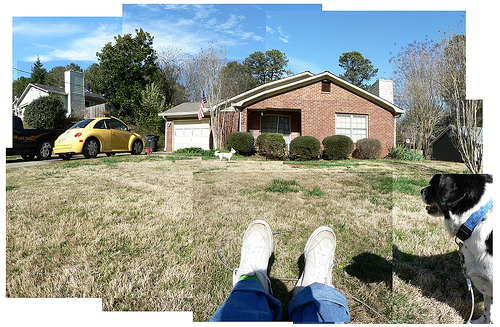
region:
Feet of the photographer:
[204, 205, 360, 325]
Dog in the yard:
[417, 166, 497, 319]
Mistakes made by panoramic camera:
[385, 170, 403, 315]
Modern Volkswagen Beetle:
[49, 104, 153, 166]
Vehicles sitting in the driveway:
[0, 100, 152, 169]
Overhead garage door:
[165, 115, 214, 155]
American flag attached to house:
[195, 88, 216, 125]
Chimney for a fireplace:
[368, 76, 395, 122]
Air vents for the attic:
[317, 71, 333, 96]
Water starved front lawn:
[112, 197, 181, 287]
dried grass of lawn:
[109, 184, 230, 251]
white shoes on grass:
[225, 208, 347, 293]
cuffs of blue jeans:
[230, 268, 356, 325]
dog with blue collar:
[445, 176, 487, 252]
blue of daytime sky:
[315, 17, 377, 47]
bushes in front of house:
[235, 132, 377, 167]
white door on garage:
[164, 109, 217, 163]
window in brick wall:
[326, 107, 376, 147]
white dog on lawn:
[206, 143, 249, 167]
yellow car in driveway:
[52, 106, 150, 173]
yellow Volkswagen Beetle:
[50, 115, 144, 157]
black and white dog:
[418, 172, 495, 317]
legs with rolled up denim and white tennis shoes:
[209, 218, 349, 320]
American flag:
[197, 91, 208, 119]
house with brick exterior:
[161, 69, 399, 161]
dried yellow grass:
[8, 151, 485, 318]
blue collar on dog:
[456, 198, 493, 245]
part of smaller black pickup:
[13, 115, 57, 159]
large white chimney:
[63, 66, 86, 118]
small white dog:
[213, 146, 235, 160]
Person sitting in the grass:
[196, 207, 374, 324]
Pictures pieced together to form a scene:
[45, 45, 481, 296]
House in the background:
[154, 72, 451, 172]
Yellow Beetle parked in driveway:
[48, 117, 151, 160]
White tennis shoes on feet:
[232, 207, 353, 311]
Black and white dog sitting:
[387, 126, 497, 306]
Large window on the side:
[315, 111, 382, 148]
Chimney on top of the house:
[364, 59, 405, 121]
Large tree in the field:
[84, 35, 177, 132]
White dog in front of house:
[207, 143, 240, 171]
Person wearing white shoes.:
[235, 220, 357, 262]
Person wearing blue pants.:
[231, 276, 320, 320]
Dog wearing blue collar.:
[448, 201, 483, 249]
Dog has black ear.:
[430, 167, 473, 217]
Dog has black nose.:
[401, 173, 425, 225]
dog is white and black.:
[432, 163, 478, 320]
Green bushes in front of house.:
[233, 127, 388, 162]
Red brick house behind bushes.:
[288, 84, 373, 146]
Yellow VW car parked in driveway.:
[77, 122, 137, 161]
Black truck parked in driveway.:
[19, 123, 74, 183]